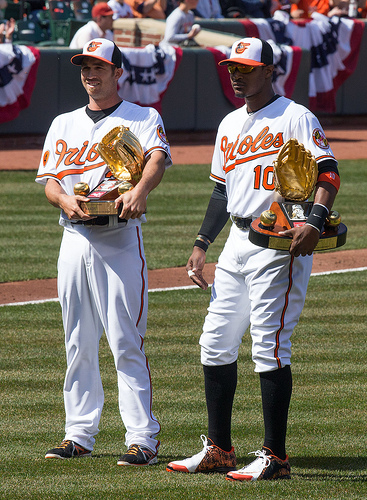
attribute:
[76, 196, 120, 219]
belt — black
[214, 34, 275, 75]
hat — orange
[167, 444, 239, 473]
shoe — white and orange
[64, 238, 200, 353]
pants — white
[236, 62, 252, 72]
lens — yellow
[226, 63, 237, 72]
lens — yellow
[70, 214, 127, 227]
belt — black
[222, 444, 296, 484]
shoe — black, white, and orange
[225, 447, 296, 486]
shoe — white and orange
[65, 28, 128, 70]
hat — orange, black, and white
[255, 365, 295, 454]
sock — long, black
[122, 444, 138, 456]
laces — yellow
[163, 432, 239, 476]
shoe — white and orange, black, white, and orange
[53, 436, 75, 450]
laces — yellow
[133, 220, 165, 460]
stripe — red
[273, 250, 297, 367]
stripe — red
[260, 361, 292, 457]
sock — black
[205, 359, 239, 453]
sock — black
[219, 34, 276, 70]
hat — orange, black, and white